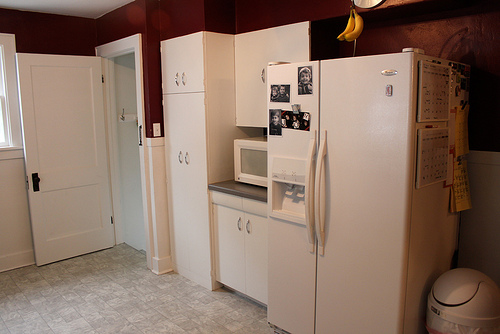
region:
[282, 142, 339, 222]
part of a handle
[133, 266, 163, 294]
part of a floor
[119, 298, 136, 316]
part of a floor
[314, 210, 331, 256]
part of a handle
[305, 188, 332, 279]
part of a handle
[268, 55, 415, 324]
this is a fridge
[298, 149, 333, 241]
these are the handles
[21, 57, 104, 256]
this is a door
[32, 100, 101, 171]
the door is white in color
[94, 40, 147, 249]
the door is open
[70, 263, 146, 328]
this is the floor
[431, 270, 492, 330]
this is a bin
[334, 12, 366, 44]
these are the banana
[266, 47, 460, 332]
the white refrigerator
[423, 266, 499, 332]
the white trash can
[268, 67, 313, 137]
the pictures on the refrigerator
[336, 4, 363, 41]
the two bananas on the refrigerator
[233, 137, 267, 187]
the white microwave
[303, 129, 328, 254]
the handles on the refrigerator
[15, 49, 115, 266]
the door in the kitchen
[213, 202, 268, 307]
the cabinet doors under the microwave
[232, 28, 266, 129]
the door to the cabinet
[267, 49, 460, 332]
the fridge is white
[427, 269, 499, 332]
trash can is white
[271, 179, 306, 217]
water dispenser on fridge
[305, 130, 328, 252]
handles on the fridge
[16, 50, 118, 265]
the door is open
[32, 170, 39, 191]
the door knob is black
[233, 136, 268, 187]
microwave on the counter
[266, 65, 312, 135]
pictures on the fridge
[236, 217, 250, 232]
handles on the cupboards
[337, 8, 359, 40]
two yellow bananas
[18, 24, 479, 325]
A small kitche area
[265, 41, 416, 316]
A white refrigerator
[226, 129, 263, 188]
A white microwave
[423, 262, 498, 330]
A white trash can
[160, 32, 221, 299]
A tall white kitchen cabinet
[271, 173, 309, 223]
Water and ice dispenser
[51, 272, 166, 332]
White and grey linoleum floor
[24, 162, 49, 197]
Dark handle and knob on white door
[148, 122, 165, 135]
White light switch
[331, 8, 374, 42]
Banana's hanging on holder on top of refrigerator